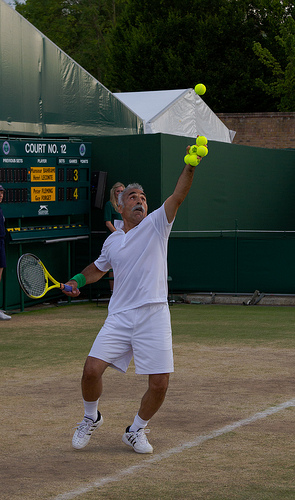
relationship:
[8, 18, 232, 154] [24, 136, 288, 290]
tents behind walls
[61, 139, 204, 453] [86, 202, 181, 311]
man wears t-shirt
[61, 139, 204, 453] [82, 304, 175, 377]
man wears shorts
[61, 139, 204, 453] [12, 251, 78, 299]
man playing tennis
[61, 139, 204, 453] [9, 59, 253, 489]
man playing tennis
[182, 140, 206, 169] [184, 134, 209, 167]
hand gripping tennis balls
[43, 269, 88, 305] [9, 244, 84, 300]
hand holding racket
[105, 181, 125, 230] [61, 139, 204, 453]
person behind man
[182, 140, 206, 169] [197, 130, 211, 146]
hand holding tennis ball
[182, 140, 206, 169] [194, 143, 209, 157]
hand holding tennis ball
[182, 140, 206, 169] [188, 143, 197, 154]
hand holding tennis ball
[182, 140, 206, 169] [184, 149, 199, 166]
hand holding tennis ball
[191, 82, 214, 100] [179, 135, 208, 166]
tennis ball floating atop held balls